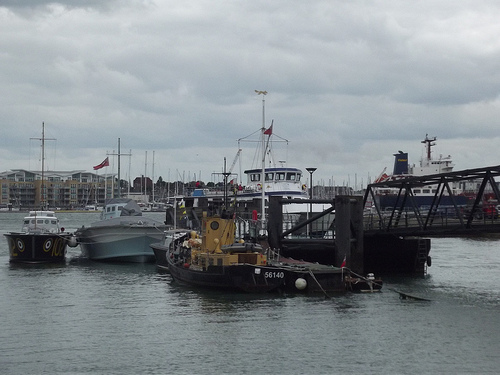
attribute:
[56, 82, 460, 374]
port — moving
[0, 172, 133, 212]
buildings — modern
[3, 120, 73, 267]
boat — brown and white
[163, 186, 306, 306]
boat — large, brown and yellow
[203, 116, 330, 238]
ship — large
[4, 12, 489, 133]
sky — cloudy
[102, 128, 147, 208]
pole — black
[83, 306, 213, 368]
water — calm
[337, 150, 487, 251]
black walkway — metal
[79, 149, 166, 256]
boat — white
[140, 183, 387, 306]
ship — black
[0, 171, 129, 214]
house — brown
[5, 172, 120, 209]
building — large, white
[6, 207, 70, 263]
ship — black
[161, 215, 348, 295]
tug boat — small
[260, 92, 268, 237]
pole — black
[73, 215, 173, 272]
white boat — light blue and white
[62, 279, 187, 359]
ripples — small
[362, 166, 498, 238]
bridge — metallic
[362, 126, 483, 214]
boat — white and blue, large